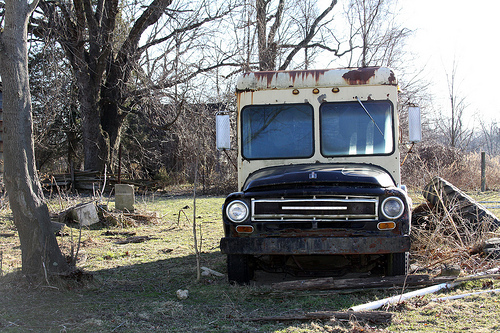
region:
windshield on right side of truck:
[318, 99, 394, 155]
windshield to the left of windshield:
[239, 103, 314, 158]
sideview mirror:
[399, 102, 424, 144]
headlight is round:
[382, 196, 404, 218]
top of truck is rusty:
[237, 66, 395, 87]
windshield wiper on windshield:
[354, 94, 391, 144]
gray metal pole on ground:
[349, 263, 499, 315]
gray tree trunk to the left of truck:
[4, 1, 76, 273]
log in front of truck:
[196, 272, 438, 294]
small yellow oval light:
[377, 221, 397, 230]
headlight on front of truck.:
[220, 198, 250, 220]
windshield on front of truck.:
[245, 112, 303, 149]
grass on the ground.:
[107, 258, 167, 305]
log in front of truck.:
[259, 278, 442, 288]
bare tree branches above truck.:
[127, 4, 208, 81]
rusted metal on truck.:
[257, 72, 374, 81]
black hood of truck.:
[265, 172, 377, 187]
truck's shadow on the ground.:
[107, 260, 208, 323]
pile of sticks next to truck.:
[431, 209, 488, 266]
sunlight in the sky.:
[466, 55, 494, 104]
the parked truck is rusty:
[218, 65, 413, 281]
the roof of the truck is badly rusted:
[230, 65, 396, 95]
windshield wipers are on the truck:
[241, 96, 393, 156]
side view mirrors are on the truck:
[210, 101, 421, 154]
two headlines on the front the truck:
[222, 187, 404, 219]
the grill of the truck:
[250, 195, 381, 220]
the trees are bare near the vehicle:
[5, 0, 495, 305]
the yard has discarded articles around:
[60, 181, 498, 321]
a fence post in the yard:
[467, 146, 493, 193]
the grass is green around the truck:
[1, 193, 498, 323]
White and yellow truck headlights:
[219, 187, 413, 238]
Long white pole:
[321, 263, 483, 328]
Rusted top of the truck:
[235, 60, 392, 92]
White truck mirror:
[211, 105, 235, 155]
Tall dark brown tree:
[55, 10, 162, 185]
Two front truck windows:
[232, 95, 398, 163]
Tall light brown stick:
[183, 132, 205, 282]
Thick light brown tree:
[1, 20, 64, 285]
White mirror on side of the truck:
[399, 100, 428, 152]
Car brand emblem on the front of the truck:
[304, 164, 321, 184]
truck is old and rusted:
[205, 50, 455, 290]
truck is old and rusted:
[206, 32, 438, 289]